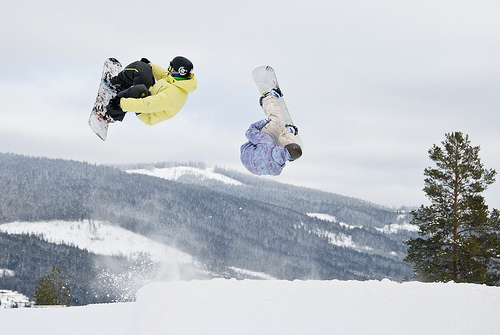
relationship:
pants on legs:
[98, 44, 160, 121] [112, 68, 138, 112]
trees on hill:
[0, 131, 498, 307] [0, 154, 499, 308]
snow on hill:
[0, 162, 497, 333] [0, 154, 499, 308]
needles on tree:
[422, 179, 434, 187] [396, 127, 497, 287]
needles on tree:
[402, 237, 412, 244] [396, 127, 497, 287]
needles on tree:
[402, 252, 412, 263] [396, 127, 497, 287]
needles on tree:
[488, 165, 495, 175] [396, 127, 497, 287]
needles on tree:
[465, 135, 470, 143] [396, 127, 497, 287]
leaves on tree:
[405, 132, 497, 282] [396, 127, 497, 287]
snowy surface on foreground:
[93, 279, 402, 331] [2, 277, 495, 333]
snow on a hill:
[176, 162, 279, 245] [3, 105, 352, 330]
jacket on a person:
[238, 116, 291, 178] [237, 85, 304, 179]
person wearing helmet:
[96, 54, 205, 124] [166, 56, 195, 77]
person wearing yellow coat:
[92, 55, 200, 126] [118, 66, 195, 124]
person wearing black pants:
[102, 55, 199, 126] [101, 54, 155, 126]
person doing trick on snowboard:
[107, 52, 196, 130] [94, 51, 124, 136]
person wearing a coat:
[239, 85, 304, 175] [237, 113, 292, 183]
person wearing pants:
[239, 85, 304, 175] [253, 92, 300, 147]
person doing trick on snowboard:
[238, 63, 305, 180] [249, 64, 299, 147]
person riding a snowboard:
[238, 63, 305, 180] [249, 64, 299, 147]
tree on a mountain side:
[403, 122, 498, 280] [334, 281, 484, 332]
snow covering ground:
[150, 286, 400, 327] [3, 157, 492, 333]